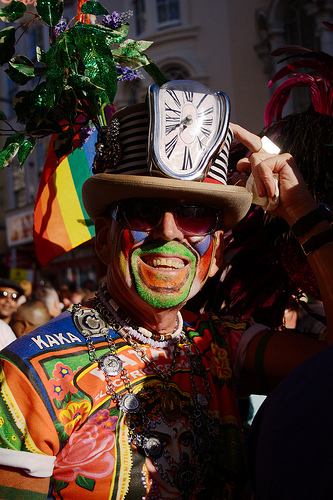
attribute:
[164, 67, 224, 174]
clock — black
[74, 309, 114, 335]
bottlecap — silver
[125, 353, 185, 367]
necklace — silver, white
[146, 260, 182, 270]
teeth — yellow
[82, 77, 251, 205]
hat — clock, black, brown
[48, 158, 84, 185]
flag — rainbow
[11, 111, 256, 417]
man — bald, smiling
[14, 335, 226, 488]
shirt — short sleeved, colorful, multi color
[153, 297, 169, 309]
beard — green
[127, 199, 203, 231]
sunglasses — dark, rose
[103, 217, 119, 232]
hair — white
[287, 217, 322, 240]
bracelet — brown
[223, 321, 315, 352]
sleeve — rolled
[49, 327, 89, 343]
letters — white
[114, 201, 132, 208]
head — bald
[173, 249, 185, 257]
paint — blue